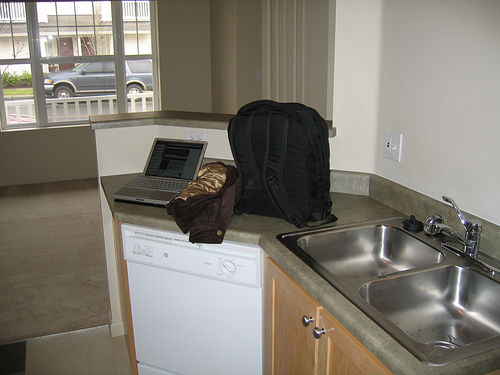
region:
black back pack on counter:
[226, 98, 338, 230]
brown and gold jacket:
[169, 162, 243, 246]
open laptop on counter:
[114, 137, 205, 207]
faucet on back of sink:
[424, 193, 482, 263]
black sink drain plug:
[398, 213, 425, 235]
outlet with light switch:
[381, 128, 406, 165]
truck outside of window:
[38, 52, 153, 99]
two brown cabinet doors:
[261, 253, 391, 373]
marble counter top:
[95, 166, 412, 236]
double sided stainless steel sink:
[280, 215, 499, 362]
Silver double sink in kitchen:
[267, 214, 498, 373]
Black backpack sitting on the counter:
[222, 86, 342, 237]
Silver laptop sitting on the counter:
[108, 135, 209, 216]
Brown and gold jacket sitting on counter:
[160, 143, 245, 246]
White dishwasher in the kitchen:
[107, 213, 274, 373]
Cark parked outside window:
[25, 34, 165, 108]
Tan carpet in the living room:
[2, 158, 104, 330]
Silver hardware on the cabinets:
[255, 258, 398, 373]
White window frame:
[6, 0, 167, 132]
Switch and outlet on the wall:
[379, 126, 404, 162]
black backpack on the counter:
[220, 99, 340, 225]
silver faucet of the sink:
[432, 216, 480, 251]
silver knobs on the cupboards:
[284, 313, 334, 343]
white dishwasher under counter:
[124, 220, 261, 374]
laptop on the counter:
[106, 125, 211, 204]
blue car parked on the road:
[37, 56, 167, 103]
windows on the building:
[22, 47, 172, 98]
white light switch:
[385, 128, 408, 163]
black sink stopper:
[398, 214, 428, 232]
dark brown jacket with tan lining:
[190, 168, 235, 258]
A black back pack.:
[226, 100, 333, 227]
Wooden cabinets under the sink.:
[266, 259, 392, 374]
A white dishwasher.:
[117, 222, 261, 373]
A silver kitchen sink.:
[276, 210, 498, 365]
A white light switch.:
[389, 129, 404, 159]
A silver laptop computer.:
[112, 137, 209, 212]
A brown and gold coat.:
[169, 153, 240, 250]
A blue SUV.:
[39, 57, 154, 100]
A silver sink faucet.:
[425, 197, 482, 259]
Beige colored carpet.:
[2, 169, 108, 339]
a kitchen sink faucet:
[416, 193, 486, 259]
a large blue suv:
[37, 45, 152, 105]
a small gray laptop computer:
[112, 138, 212, 206]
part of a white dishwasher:
[120, 219, 267, 374]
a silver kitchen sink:
[275, 213, 499, 370]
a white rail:
[1, 94, 154, 120]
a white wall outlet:
[382, 126, 406, 161]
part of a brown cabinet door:
[257, 259, 318, 374]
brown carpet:
[5, 176, 111, 342]